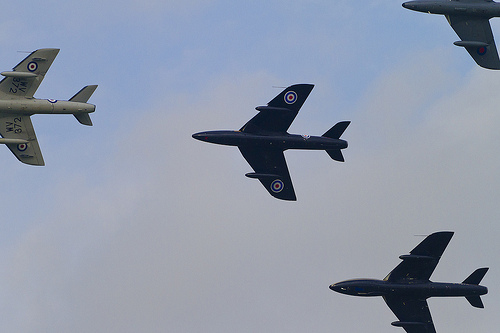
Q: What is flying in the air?
A: Jets.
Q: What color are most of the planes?
A: Dark blue.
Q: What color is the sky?
A: Blue.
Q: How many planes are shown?
A: 4.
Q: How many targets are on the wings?
A: Four.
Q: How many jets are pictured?
A: 4.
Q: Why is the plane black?
A: Design.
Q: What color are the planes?
A: Black and grey.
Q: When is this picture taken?
A: During the day.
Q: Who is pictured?
A: No one.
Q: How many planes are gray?
A: One.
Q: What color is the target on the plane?
A: Blue red and white.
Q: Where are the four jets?
A: Sky.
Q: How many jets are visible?
A: 4.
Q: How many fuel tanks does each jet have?
A: 2.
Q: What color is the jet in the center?
A: Dark blue.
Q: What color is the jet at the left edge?
A: Gray.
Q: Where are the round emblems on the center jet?
A: Bottom of each wing.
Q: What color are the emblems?
A: Red, white, and blue.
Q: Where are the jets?
A: In the sky.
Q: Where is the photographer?
A: Below the jets.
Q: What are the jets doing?
A: Flying in formation.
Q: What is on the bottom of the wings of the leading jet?
A: Numbers and letters.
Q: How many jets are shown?
A: Four.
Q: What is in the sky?
A: Jets.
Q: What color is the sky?
A: It is blue.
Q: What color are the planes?
A: Blue and white.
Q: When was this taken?
A: During the daytime.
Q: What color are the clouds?
A: White.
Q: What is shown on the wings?
A: Circles.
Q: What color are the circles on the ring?
A: White and red.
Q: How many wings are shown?
A: Seven.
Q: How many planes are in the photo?
A: Four.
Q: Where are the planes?
A: Sky.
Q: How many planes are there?
A: Four.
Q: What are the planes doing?
A: Flying.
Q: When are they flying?
A: Daytime.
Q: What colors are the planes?
A: Silver and black.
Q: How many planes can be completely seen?
A: One.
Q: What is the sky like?
A: Blue and cloudy.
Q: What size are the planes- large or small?
A: Small.